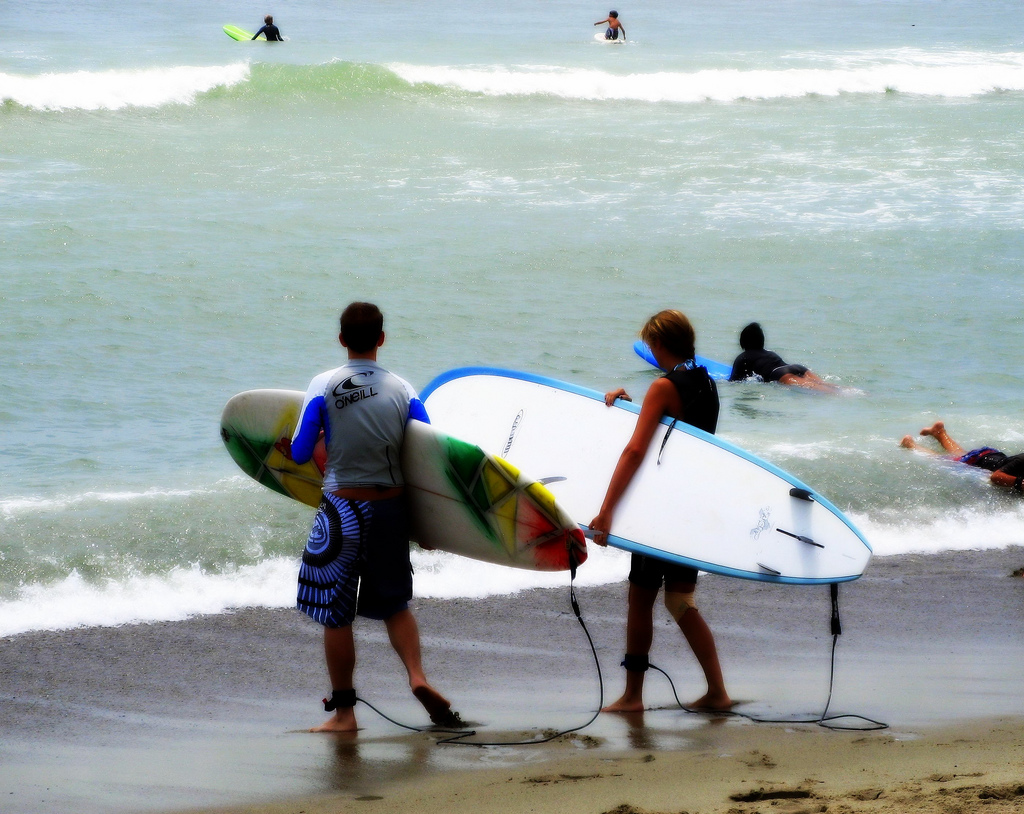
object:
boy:
[290, 301, 452, 731]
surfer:
[249, 14, 284, 42]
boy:
[594, 10, 626, 41]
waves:
[0, 40, 1024, 116]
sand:
[0, 552, 1024, 814]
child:
[900, 421, 1024, 492]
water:
[484, 111, 613, 209]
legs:
[309, 606, 452, 732]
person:
[595, 307, 732, 711]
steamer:
[750, 505, 770, 541]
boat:
[221, 389, 590, 572]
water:
[3, 470, 276, 647]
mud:
[254, 714, 1024, 814]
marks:
[726, 786, 813, 805]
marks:
[945, 766, 1024, 809]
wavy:
[0, 48, 1024, 642]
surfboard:
[633, 339, 745, 382]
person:
[728, 322, 848, 393]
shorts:
[298, 486, 415, 629]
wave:
[0, 420, 1024, 645]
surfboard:
[421, 366, 876, 585]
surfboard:
[224, 24, 271, 42]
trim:
[436, 366, 519, 389]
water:
[0, 0, 1024, 771]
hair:
[640, 309, 697, 359]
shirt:
[660, 367, 720, 438]